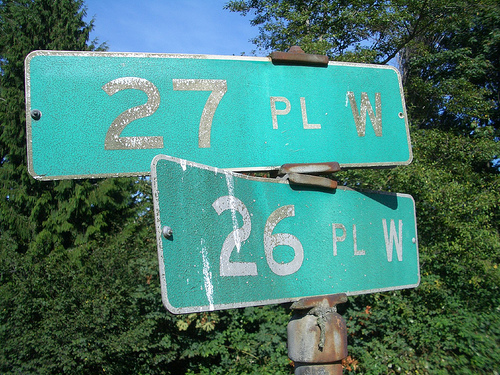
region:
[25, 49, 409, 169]
Green and white street sign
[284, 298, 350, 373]
Pole underneath two street signs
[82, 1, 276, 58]
Clear blue sky behind trees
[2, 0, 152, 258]
Tall pine tree in the background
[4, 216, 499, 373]
Bushes behind the street signs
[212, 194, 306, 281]
Number 26 on a street sign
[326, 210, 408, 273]
Letters on a street sign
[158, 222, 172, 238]
Metal screw holding sign on a post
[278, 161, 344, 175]
Metal on the post is rusting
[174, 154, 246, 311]
Bird droppings dried on a sign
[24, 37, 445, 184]
this is a sign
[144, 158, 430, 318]
this is a sign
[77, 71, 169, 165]
this a number on sign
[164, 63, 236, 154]
this a number on sign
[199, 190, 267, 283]
this a number on sign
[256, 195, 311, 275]
this a number on sign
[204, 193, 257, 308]
a number on the sign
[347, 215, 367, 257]
a number on the sign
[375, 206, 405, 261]
a number on the sign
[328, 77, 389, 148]
a number on the sign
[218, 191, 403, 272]
white lettering on a green sign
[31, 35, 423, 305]
two green street markers on a post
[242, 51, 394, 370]
grey metal post holding street signs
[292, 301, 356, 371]
rust on the grey metal post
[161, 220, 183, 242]
grey bolt in the street marker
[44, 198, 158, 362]
trees growing behind the street marker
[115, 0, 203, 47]
clear blue skies over the scene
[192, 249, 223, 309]
dried white bird poop on the sign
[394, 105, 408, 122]
an empty bolt hole in the street sign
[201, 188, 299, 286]
white numbers on the green street marker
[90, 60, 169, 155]
a number on the sign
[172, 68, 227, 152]
a number on the sign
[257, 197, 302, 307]
a number on the sign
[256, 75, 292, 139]
a letter on the sign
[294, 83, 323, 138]
a number on the sign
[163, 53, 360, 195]
this is a post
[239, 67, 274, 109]
the post is green in color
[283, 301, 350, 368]
this is a pole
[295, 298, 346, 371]
the pole is rusty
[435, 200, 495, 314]
the tree is leafy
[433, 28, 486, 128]
the leaves are green in color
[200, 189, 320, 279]
it is written 26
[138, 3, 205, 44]
this is the sky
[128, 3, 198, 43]
the sky is blue in color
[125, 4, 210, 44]
the sky is clear